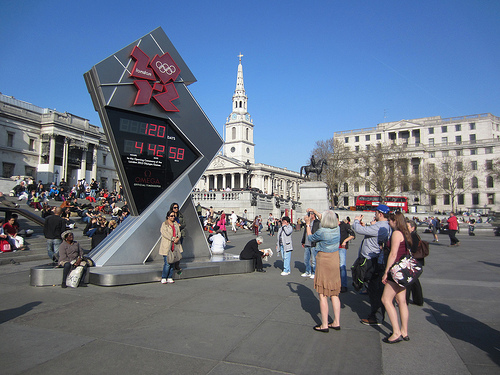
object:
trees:
[364, 140, 398, 207]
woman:
[376, 208, 424, 348]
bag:
[388, 250, 422, 293]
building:
[330, 106, 499, 220]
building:
[0, 93, 120, 196]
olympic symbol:
[155, 60, 177, 76]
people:
[306, 194, 446, 347]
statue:
[301, 157, 326, 180]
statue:
[80, 26, 223, 268]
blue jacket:
[307, 223, 344, 254]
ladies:
[154, 200, 190, 289]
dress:
[316, 245, 341, 297]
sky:
[0, 0, 500, 175]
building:
[184, 44, 308, 231]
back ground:
[208, 216, 500, 251]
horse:
[299, 157, 330, 182]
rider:
[307, 155, 321, 173]